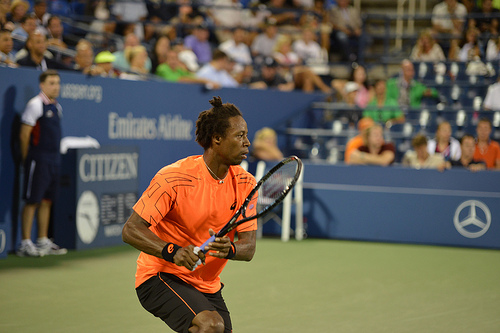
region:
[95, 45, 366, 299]
tennis player is black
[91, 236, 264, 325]
the shorts are black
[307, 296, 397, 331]
the court is green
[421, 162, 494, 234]
Mercedes benz is a sponsor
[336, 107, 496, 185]
the audience is watching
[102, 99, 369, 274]
the player has an orange shirt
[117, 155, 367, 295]
his racket is black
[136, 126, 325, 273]
the tennis player is male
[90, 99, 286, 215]
emirates airlines is a sponsor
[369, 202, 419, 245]
the wall is blue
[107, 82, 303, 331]
tennis player in a match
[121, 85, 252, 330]
tennis player wearing orange shirt and black shorts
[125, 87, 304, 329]
tennis player holding a racket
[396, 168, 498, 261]
Mercedes Benz is a sponsor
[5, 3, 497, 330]
people in the stands watching a tennis match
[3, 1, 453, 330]
people watching an evening tennis match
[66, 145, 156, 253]
Citizen watches are a sponsor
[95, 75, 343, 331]
the tennis player is focussed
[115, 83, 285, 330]
male tennis player at a match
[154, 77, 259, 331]
male tennis player is sweaty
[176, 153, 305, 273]
a tennis racket with black frame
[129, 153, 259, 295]
an orange tee shirt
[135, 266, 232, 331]
a pair of black shorts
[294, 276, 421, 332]
a green tennis court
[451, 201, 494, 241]
a white logo in background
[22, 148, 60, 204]
dark blue shorts with white stripe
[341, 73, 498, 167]
audience watching tennis match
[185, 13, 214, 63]
man wearing purple shirt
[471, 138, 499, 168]
an orange tee shirt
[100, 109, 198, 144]
white words in background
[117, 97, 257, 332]
Male tennis player preparing to hit ball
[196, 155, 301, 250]
Black tennis racket held by male player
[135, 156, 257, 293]
Orange shirt on male tennis player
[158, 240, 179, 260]
Black wristband with orange design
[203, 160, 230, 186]
Necklace on male tennis player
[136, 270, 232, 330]
Black shorts with orange stripe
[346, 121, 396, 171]
Spectator at tennis match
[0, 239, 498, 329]
Green backcourt surface of tennis court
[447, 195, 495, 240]
Mercedes logo on tennis court wall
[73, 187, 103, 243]
Clock at tennis court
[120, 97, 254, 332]
A black guy wearing an orange shirt playing tennis.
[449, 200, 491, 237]
A Mercedes symbol on the blue wall.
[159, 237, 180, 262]
Black and orange sweatband on a man playing tennis arm.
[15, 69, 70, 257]
A brown haired guy standing against a blue wall.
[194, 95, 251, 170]
Black man's head who is playing tennis.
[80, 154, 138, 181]
The word CITIZEN on the blue wall.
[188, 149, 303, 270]
Black tennis racket a black man is holding.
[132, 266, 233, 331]
Black shorts with orange stripe.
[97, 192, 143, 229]
A clock on a blue wall under a CITIZEN sign.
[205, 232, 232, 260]
A black man's left hand.